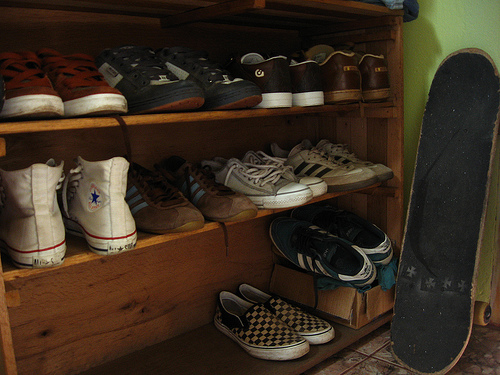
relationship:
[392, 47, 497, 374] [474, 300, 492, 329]
skateboard has a wheel